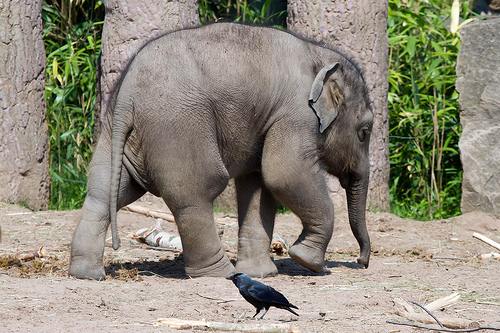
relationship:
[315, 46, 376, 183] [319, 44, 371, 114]
head has hair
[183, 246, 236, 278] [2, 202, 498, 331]
foot on ground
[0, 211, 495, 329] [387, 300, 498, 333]
road has a twig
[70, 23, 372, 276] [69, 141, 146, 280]
elephant has legs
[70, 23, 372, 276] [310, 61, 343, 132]
elephant has a ear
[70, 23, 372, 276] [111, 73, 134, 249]
elephant has a tail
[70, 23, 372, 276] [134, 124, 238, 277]
elephant has a leg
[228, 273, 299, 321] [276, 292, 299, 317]
bird has a tail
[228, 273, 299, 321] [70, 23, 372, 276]
bird next to elephant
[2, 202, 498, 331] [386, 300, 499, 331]
ground has a stick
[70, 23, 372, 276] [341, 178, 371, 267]
elephant has a trunk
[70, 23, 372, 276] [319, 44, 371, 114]
elephant has hair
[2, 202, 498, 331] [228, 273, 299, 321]
ground has a bird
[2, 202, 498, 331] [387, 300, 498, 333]
ground has a twig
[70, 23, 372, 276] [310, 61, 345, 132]
elephant has ears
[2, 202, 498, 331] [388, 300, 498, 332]
ground has tree branches